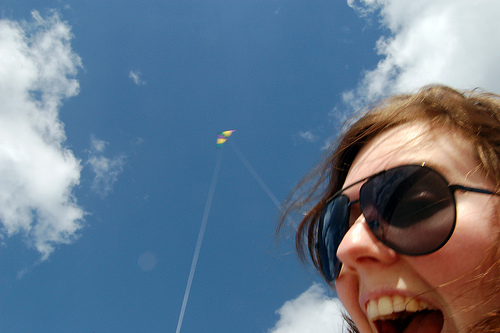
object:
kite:
[217, 129, 236, 148]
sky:
[85, 5, 329, 124]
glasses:
[316, 165, 500, 285]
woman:
[273, 83, 499, 333]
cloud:
[0, 2, 85, 266]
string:
[171, 147, 226, 333]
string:
[236, 147, 283, 215]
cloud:
[128, 69, 146, 87]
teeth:
[376, 298, 392, 316]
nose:
[336, 216, 399, 268]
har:
[326, 80, 498, 179]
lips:
[360, 287, 440, 313]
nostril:
[357, 256, 380, 265]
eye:
[402, 194, 433, 215]